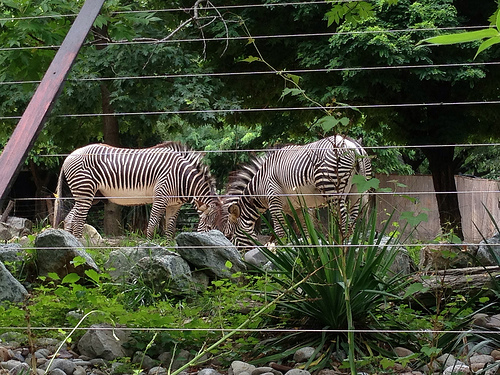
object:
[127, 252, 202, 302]
rock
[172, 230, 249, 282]
rock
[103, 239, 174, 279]
rock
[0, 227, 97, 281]
rock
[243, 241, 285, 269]
rock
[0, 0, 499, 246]
trees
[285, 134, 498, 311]
flower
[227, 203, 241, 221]
ear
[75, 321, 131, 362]
rock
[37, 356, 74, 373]
rock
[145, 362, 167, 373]
rock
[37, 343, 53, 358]
rock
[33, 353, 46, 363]
rock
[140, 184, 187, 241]
legs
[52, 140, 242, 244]
zebra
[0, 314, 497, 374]
gravel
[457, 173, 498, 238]
fence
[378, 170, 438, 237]
fence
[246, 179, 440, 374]
bush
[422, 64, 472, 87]
leaves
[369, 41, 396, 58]
leaves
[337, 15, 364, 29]
leaves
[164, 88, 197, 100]
leaves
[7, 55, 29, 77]
leaves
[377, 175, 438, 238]
wall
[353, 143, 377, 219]
tail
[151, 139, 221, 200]
mane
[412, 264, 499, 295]
log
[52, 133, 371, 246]
zebras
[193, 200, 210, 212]
ear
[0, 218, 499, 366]
grass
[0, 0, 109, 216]
post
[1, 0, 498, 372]
fence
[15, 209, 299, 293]
ground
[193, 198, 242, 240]
head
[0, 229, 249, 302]
rocks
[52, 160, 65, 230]
tail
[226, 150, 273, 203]
mane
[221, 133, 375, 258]
zebra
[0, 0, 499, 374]
zoo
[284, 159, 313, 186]
stripes